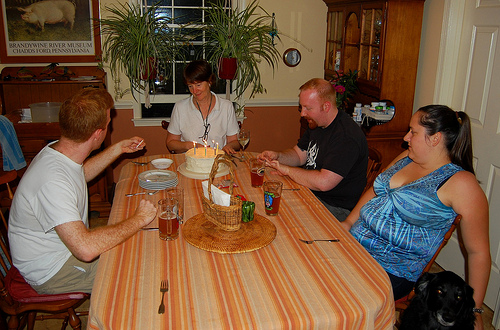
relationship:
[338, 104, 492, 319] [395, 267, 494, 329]
lady petting dog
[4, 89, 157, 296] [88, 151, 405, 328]
guy sitting aroound table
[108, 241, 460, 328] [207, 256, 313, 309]
tablecloth on table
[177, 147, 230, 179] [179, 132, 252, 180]
birthday cake with candles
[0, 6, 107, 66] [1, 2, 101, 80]
picture in frame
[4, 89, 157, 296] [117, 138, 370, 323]
guy at table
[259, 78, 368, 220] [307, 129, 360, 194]
guy with shirt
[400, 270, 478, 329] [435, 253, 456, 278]
black dog sitting on floor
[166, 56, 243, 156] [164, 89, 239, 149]
woman wearing shirt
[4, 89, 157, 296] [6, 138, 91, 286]
guy wearing t-shirt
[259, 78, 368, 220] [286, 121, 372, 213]
guy wearing shirt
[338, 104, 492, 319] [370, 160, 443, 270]
lady wearing top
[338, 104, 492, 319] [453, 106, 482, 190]
lady wearing ponytail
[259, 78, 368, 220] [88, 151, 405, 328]
guy sitting at table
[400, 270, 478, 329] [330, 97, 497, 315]
black dog sitting next woman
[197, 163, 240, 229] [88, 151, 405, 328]
basket on table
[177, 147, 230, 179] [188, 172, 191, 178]
birthday cake on plate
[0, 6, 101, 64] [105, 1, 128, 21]
picture on wall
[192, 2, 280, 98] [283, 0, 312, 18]
plant hanging from ceiling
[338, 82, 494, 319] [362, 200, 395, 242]
lady with muffintop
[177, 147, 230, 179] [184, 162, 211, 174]
birthday cake with icing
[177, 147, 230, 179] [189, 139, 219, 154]
birthday cake with candles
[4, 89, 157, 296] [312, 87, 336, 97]
guy with hair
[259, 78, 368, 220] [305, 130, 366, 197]
guy wearing shirt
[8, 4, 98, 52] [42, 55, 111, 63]
poster in frame